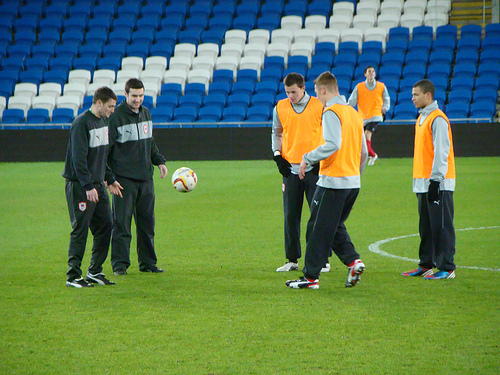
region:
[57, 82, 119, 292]
man in black playing soccer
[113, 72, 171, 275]
man in black playing soccer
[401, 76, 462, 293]
man with yellow vest playing soccer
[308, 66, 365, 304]
man with yellow vest playing soccer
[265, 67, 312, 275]
man with yellow vest playing soccer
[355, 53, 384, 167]
man with yellow vest watching soccer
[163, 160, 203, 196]
red and white soccer ball in air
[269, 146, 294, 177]
black gloves on man with yellow vest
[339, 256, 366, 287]
soccer cleat on man with yellow vest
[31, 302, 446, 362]
green grass on soccer field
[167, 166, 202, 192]
a red and white soccer ball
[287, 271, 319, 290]
a man's tennis shoe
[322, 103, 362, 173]
a man's yellow vest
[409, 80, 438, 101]
a man's short cut black hair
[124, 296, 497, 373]
part of a green grassy field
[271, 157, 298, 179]
a black glove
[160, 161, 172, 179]
the hand of a man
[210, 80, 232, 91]
a blue stadium seat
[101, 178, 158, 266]
a man's pants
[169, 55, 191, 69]
a white stadium seat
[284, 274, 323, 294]
white black and red sports shoes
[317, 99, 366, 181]
yellow vest on man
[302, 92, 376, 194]
grey turtleneck shirt and a yellow vest on man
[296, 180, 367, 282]
black sweat pants on man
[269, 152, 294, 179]
black men's glove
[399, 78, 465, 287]
soccer player standing on the field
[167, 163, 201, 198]
white and red soccer ball up in the air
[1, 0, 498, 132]
blue adn white seats of a stadium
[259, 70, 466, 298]
soccer players on the field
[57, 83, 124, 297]
player in grey outfit and black shoes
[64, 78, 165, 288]
Two men standing beside each other.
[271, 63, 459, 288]
Four men dressed in the same uniform.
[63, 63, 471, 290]
A group of players on a soccer field.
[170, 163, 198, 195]
A soccer ball in the air.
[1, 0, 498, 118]
Blue and white stadium seats.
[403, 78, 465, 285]
One man standing on a soccer field.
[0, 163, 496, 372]
A green soccer field.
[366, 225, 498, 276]
White line on a green field.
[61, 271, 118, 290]
A pair of black and white soccer cleats.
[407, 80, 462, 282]
A player wearing an orange vest.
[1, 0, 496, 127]
Empty blue and white seats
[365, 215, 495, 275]
White lines on the grass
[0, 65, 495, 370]
People standing on a soccer field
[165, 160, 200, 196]
A round soccer ball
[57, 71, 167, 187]
Two men wearing black sweatshirts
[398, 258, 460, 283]
A pair of colorful sneakers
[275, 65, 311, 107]
Man has brown hair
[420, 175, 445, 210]
A glove is black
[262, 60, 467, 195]
Four men wearing orange and gray shirts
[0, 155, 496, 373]
Green grass on the soccer field